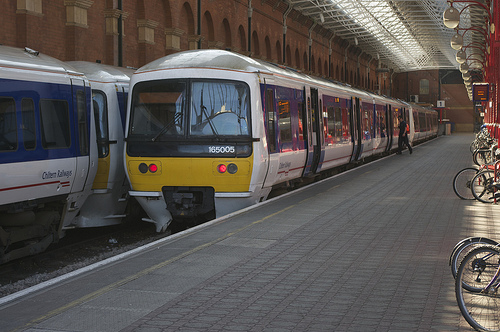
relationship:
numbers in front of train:
[209, 144, 237, 153] [123, 52, 439, 197]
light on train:
[214, 158, 234, 179] [123, 52, 439, 197]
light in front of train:
[214, 158, 234, 179] [123, 52, 439, 197]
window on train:
[268, 97, 303, 151] [123, 52, 439, 197]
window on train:
[125, 83, 177, 139] [123, 52, 439, 197]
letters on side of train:
[37, 169, 78, 186] [10, 55, 123, 237]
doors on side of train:
[377, 93, 397, 159] [123, 52, 439, 197]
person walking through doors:
[393, 109, 421, 163] [377, 93, 397, 159]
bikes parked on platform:
[465, 127, 499, 221] [360, 125, 500, 312]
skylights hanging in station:
[440, 7, 481, 100] [49, 17, 500, 202]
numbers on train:
[209, 144, 237, 153] [123, 52, 439, 197]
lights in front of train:
[141, 160, 231, 180] [123, 52, 439, 197]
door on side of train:
[301, 87, 326, 175] [123, 52, 439, 197]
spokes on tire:
[468, 180, 482, 197] [450, 165, 484, 206]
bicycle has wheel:
[440, 216, 499, 331] [455, 253, 499, 322]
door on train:
[301, 87, 326, 175] [123, 52, 439, 197]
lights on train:
[216, 164, 227, 172] [123, 52, 439, 197]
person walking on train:
[393, 109, 421, 163] [123, 52, 439, 197]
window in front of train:
[125, 83, 177, 139] [123, 52, 439, 197]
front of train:
[128, 68, 252, 192] [123, 52, 439, 197]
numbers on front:
[209, 144, 237, 153] [128, 68, 252, 192]